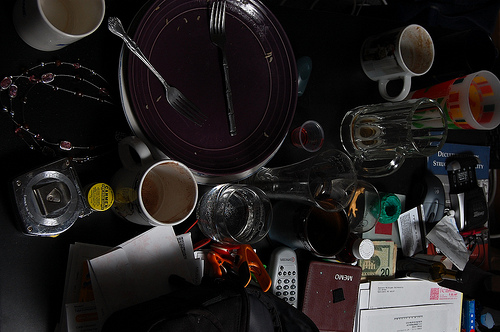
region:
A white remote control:
[272, 238, 311, 315]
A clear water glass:
[201, 185, 277, 247]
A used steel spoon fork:
[121, 27, 201, 122]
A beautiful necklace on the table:
[9, 60, 122, 168]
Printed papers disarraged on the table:
[363, 273, 470, 330]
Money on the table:
[365, 228, 405, 278]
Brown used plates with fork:
[141, 6, 301, 173]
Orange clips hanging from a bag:
[209, 248, 276, 289]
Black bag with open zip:
[139, 286, 326, 328]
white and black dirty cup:
[367, 25, 441, 110]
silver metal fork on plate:
[208, 3, 243, 145]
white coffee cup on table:
[20, 0, 105, 60]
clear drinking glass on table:
[191, 179, 271, 245]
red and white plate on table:
[125, 8, 307, 175]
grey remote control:
[273, 248, 303, 313]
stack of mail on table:
[355, 277, 465, 329]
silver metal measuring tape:
[10, 155, 94, 245]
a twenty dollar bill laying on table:
[355, 238, 400, 278]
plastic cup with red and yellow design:
[410, 71, 497, 133]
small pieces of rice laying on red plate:
[152, 10, 204, 34]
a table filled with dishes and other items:
[2, 2, 497, 329]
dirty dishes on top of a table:
[11, 0, 496, 244]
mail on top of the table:
[353, 274, 463, 330]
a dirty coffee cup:
[114, 135, 198, 227]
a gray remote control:
[271, 249, 299, 307]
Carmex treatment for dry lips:
[87, 180, 114, 211]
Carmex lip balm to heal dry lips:
[86, 181, 114, 212]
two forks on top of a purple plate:
[107, 0, 237, 137]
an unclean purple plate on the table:
[123, 2, 300, 177]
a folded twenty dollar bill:
[360, 240, 395, 277]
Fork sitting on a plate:
[208, 2, 245, 143]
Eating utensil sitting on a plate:
[107, 14, 202, 124]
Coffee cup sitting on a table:
[107, 133, 202, 227]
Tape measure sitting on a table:
[4, 154, 94, 245]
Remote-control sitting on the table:
[265, 243, 302, 323]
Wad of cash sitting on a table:
[358, 236, 397, 281]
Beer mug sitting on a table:
[335, 93, 452, 178]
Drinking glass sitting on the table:
[200, 185, 278, 245]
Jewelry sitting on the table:
[2, 52, 115, 157]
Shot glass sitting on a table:
[292, 115, 327, 155]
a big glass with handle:
[320, 79, 452, 191]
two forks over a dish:
[104, 0, 264, 157]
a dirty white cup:
[359, 13, 439, 110]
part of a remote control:
[270, 237, 308, 316]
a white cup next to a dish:
[8, 0, 108, 62]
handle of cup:
[350, 143, 408, 188]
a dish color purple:
[116, 5, 308, 176]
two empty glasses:
[264, 141, 389, 236]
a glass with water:
[200, 176, 281, 254]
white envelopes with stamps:
[356, 271, 468, 329]